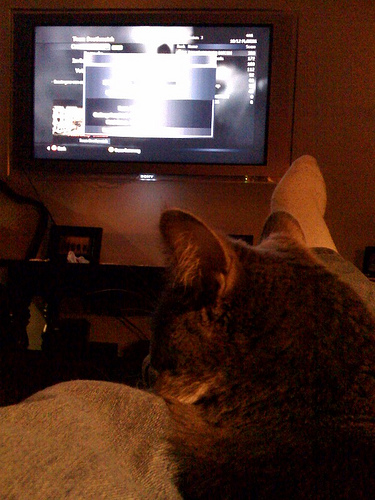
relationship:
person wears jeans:
[2, 156, 375, 499] [1, 249, 373, 498]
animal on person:
[141, 209, 375, 498] [2, 156, 369, 499]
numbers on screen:
[241, 32, 261, 111] [4, 0, 302, 189]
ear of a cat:
[160, 209, 238, 306] [151, 182, 372, 499]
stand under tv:
[2, 255, 172, 375] [6, 4, 299, 191]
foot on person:
[265, 147, 333, 252] [256, 146, 374, 327]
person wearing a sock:
[2, 156, 369, 499] [272, 154, 335, 249]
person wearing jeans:
[2, 156, 375, 499] [130, 250, 363, 434]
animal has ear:
[141, 209, 375, 498] [156, 200, 244, 307]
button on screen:
[104, 144, 142, 154] [33, 28, 268, 164]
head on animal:
[169, 251, 365, 379] [141, 209, 375, 498]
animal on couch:
[141, 209, 375, 498] [3, 345, 364, 489]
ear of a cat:
[258, 206, 307, 241] [133, 198, 373, 498]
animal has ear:
[141, 209, 375, 498] [255, 209, 313, 256]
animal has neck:
[141, 209, 375, 498] [204, 343, 268, 406]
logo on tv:
[138, 172, 157, 178] [7, 11, 273, 180]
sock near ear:
[264, 143, 343, 267] [258, 209, 307, 241]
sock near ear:
[264, 143, 343, 267] [144, 196, 249, 306]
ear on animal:
[258, 209, 307, 241] [123, 196, 373, 498]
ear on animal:
[144, 196, 249, 306] [123, 196, 373, 498]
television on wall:
[8, 9, 297, 185] [5, 8, 358, 291]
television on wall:
[7, 10, 265, 183] [15, 15, 373, 248]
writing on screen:
[57, 116, 152, 171] [28, 22, 272, 149]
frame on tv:
[15, 9, 303, 180] [7, 11, 273, 180]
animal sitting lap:
[141, 209, 375, 498] [4, 356, 194, 492]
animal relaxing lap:
[123, 196, 373, 498] [7, 362, 196, 482]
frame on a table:
[40, 218, 106, 266] [0, 234, 253, 387]